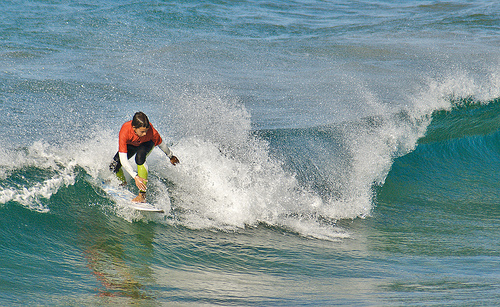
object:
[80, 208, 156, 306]
reflection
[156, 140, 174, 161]
sleeve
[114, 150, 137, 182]
sleeve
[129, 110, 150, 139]
head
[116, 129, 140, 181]
arm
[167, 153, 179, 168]
hand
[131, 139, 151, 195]
leg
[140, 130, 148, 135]
eye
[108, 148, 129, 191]
leg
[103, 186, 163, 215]
surfboard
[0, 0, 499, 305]
water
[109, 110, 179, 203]
boy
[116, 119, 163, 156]
dress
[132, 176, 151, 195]
boy hand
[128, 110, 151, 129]
boy hair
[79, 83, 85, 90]
droplet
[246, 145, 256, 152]
water droplet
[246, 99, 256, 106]
water droplet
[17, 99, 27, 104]
water droplet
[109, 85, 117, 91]
water droplet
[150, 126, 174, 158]
arm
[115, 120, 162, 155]
shirt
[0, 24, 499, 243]
wave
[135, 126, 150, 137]
face